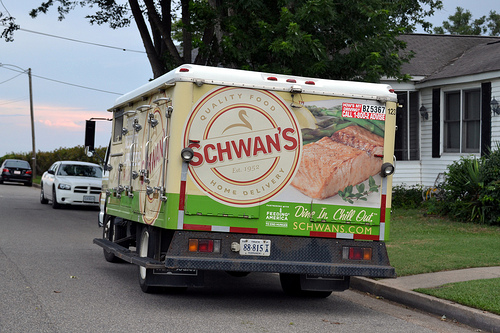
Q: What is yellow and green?
A: The truck.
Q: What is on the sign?
A: Food.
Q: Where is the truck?
A: Next to a curb.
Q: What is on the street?
A: A truck.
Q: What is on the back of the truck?
A: A logo.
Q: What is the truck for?
A: Food delivery.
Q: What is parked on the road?
A: A truck.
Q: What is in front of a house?
A: Truck.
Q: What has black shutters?
A: The white house.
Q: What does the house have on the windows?
A: Black shutters.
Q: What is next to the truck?
A: A lawn.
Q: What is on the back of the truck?
A: A bumper.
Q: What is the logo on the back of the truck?
A: Schwan's.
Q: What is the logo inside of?
A: A circle.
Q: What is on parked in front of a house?
A: A truck.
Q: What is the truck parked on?
A: The street.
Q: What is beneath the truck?
A: Tires.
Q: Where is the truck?
A: In front of the house.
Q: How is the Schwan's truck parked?
A: Beside the street curb.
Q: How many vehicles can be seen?
A: 3.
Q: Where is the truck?
A: In the street.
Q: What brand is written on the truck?
A: Schwan's.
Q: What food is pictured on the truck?
A: Salmon.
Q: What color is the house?
A: White.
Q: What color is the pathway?
A: Gray.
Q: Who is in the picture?
A: No one.